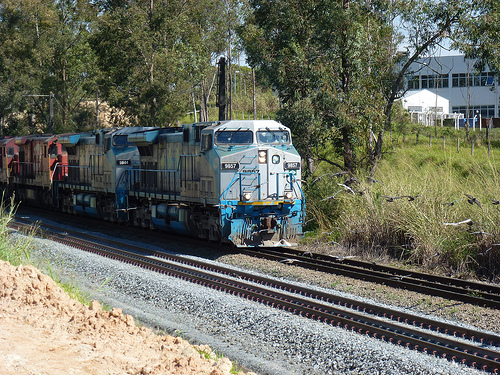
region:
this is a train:
[120, 117, 282, 233]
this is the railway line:
[278, 289, 358, 326]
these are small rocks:
[287, 323, 354, 369]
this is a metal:
[357, 262, 389, 287]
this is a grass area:
[412, 136, 482, 209]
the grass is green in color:
[421, 140, 440, 177]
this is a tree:
[296, 29, 371, 133]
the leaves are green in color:
[320, 54, 345, 68]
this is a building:
[431, 70, 483, 100]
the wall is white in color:
[453, 89, 475, 101]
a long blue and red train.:
[0, 114, 315, 248]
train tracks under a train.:
[3, 201, 498, 371]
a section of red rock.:
[0, 253, 254, 370]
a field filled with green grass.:
[288, 119, 498, 277]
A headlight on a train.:
[255, 139, 270, 166]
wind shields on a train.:
[198, 124, 291, 149]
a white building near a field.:
[388, 84, 455, 131]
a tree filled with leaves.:
[233, 1, 395, 176]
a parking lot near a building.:
[425, 106, 497, 134]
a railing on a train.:
[109, 164, 195, 200]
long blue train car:
[98, 117, 313, 234]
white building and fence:
[376, 35, 498, 136]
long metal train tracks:
[85, 225, 470, 346]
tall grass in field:
[343, 122, 480, 257]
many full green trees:
[143, 19, 472, 147]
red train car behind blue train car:
[26, 116, 66, 189]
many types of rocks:
[33, 273, 307, 353]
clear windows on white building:
[393, 57, 495, 97]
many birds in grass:
[316, 145, 466, 245]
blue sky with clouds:
[386, 12, 486, 47]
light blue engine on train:
[56, 102, 319, 256]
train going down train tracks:
[1, 110, 306, 265]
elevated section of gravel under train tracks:
[0, 199, 498, 374]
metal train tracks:
[1, 196, 498, 374]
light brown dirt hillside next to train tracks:
[1, 256, 258, 374]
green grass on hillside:
[0, 186, 102, 314]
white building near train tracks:
[297, 46, 498, 130]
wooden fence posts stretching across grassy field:
[365, 121, 498, 159]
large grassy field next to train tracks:
[131, 80, 498, 243]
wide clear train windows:
[212, 124, 294, 147]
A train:
[116, 121, 343, 283]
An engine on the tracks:
[50, 121, 392, 231]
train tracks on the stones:
[202, 261, 290, 348]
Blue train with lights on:
[167, 113, 314, 229]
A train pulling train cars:
[49, 122, 321, 374]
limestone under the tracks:
[178, 294, 260, 369]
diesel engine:
[132, 126, 293, 264]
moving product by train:
[14, 62, 328, 279]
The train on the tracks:
[33, 81, 326, 247]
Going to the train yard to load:
[126, 9, 347, 279]